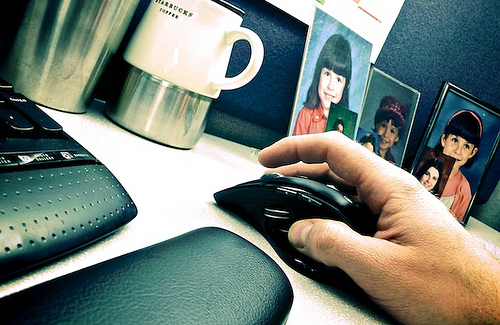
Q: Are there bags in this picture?
A: No, there are no bags.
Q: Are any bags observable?
A: No, there are no bags.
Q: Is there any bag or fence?
A: No, there are no bags or fences.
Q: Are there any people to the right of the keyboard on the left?
A: Yes, there is a person to the right of the keyboard.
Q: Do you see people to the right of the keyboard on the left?
A: Yes, there is a person to the right of the keyboard.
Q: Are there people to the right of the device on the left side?
A: Yes, there is a person to the right of the keyboard.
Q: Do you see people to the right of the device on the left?
A: Yes, there is a person to the right of the keyboard.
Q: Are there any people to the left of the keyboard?
A: No, the person is to the right of the keyboard.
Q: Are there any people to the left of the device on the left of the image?
A: No, the person is to the right of the keyboard.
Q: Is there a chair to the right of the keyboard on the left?
A: No, there is a person to the right of the keyboard.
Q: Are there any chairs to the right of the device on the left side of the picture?
A: No, there is a person to the right of the keyboard.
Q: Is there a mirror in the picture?
A: No, there are no mirrors.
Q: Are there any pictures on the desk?
A: Yes, there is a picture on the desk.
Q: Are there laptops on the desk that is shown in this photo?
A: No, there is a picture on the desk.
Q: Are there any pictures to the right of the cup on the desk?
A: Yes, there is a picture to the right of the cup.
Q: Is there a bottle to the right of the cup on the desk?
A: No, there is a picture to the right of the cup.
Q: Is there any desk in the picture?
A: Yes, there is a desk.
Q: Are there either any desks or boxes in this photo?
A: Yes, there is a desk.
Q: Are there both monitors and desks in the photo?
A: No, there is a desk but no monitors.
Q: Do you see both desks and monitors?
A: No, there is a desk but no monitors.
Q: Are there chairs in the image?
A: No, there are no chairs.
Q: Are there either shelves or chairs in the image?
A: No, there are no chairs or shelves.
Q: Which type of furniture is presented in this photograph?
A: The furniture is a desk.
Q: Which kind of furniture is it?
A: The piece of furniture is a desk.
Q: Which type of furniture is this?
A: This is a desk.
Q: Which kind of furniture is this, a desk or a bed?
A: This is a desk.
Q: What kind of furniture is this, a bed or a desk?
A: This is a desk.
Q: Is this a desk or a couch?
A: This is a desk.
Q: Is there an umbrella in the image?
A: No, there are no umbrellas.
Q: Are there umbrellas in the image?
A: No, there are no umbrellas.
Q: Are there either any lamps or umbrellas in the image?
A: No, there are no umbrellas or lamps.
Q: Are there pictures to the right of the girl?
A: Yes, there is a picture to the right of the girl.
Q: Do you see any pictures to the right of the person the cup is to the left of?
A: Yes, there is a picture to the right of the girl.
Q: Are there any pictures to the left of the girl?
A: No, the picture is to the right of the girl.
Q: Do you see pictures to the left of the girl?
A: No, the picture is to the right of the girl.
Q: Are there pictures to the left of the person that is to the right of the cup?
A: No, the picture is to the right of the girl.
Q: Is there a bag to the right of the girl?
A: No, there is a picture to the right of the girl.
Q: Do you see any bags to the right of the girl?
A: No, there is a picture to the right of the girl.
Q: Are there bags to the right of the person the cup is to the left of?
A: No, there is a picture to the right of the girl.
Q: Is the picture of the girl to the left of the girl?
A: No, the picture is to the right of the girl.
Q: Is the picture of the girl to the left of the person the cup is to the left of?
A: No, the picture is to the right of the girl.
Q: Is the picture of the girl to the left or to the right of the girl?
A: The picture is to the right of the girl.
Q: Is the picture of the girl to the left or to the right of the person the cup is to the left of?
A: The picture is to the right of the girl.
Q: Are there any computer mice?
A: Yes, there is a computer mouse.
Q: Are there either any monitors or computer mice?
A: Yes, there is a computer mouse.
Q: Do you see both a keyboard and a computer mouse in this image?
A: Yes, there are both a computer mouse and a keyboard.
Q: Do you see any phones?
A: No, there are no phones.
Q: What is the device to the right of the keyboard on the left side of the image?
A: The device is a computer mouse.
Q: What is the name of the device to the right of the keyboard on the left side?
A: The device is a computer mouse.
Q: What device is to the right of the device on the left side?
A: The device is a computer mouse.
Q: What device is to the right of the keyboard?
A: The device is a computer mouse.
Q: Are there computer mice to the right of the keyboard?
A: Yes, there is a computer mouse to the right of the keyboard.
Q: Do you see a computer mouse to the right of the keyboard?
A: Yes, there is a computer mouse to the right of the keyboard.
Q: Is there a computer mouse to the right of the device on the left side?
A: Yes, there is a computer mouse to the right of the keyboard.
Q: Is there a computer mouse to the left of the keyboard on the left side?
A: No, the computer mouse is to the right of the keyboard.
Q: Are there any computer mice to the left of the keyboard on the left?
A: No, the computer mouse is to the right of the keyboard.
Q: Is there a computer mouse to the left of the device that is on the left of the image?
A: No, the computer mouse is to the right of the keyboard.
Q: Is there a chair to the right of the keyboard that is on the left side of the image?
A: No, there is a computer mouse to the right of the keyboard.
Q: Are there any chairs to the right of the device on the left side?
A: No, there is a computer mouse to the right of the keyboard.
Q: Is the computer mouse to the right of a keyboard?
A: Yes, the computer mouse is to the right of a keyboard.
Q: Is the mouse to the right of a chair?
A: No, the mouse is to the right of a keyboard.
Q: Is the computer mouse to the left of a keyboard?
A: No, the computer mouse is to the right of a keyboard.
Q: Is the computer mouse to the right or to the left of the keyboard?
A: The computer mouse is to the right of the keyboard.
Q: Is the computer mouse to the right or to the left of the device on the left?
A: The computer mouse is to the right of the keyboard.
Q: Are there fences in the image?
A: No, there are no fences.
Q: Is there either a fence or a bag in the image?
A: No, there are no fences or bags.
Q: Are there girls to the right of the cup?
A: Yes, there is a girl to the right of the cup.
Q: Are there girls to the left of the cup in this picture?
A: No, the girl is to the right of the cup.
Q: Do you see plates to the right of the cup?
A: No, there is a girl to the right of the cup.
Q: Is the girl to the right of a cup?
A: Yes, the girl is to the right of a cup.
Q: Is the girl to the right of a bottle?
A: No, the girl is to the right of a cup.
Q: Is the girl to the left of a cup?
A: No, the girl is to the right of a cup.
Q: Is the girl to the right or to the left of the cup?
A: The girl is to the right of the cup.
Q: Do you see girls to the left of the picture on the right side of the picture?
A: Yes, there is a girl to the left of the picture.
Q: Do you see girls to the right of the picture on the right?
A: No, the girl is to the left of the picture.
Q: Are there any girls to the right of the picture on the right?
A: No, the girl is to the left of the picture.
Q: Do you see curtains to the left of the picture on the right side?
A: No, there is a girl to the left of the picture.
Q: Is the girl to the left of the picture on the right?
A: Yes, the girl is to the left of the picture.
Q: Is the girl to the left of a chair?
A: No, the girl is to the left of the picture.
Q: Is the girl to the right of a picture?
A: No, the girl is to the left of a picture.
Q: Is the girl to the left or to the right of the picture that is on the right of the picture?
A: The girl is to the left of the picture.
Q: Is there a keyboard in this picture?
A: Yes, there is a keyboard.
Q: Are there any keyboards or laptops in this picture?
A: Yes, there is a keyboard.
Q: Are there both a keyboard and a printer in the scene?
A: No, there is a keyboard but no printers.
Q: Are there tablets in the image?
A: No, there are no tablets.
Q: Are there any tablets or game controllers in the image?
A: No, there are no tablets or game controllers.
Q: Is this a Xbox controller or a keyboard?
A: This is a keyboard.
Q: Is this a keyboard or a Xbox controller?
A: This is a keyboard.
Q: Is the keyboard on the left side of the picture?
A: Yes, the keyboard is on the left of the image.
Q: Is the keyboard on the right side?
A: No, the keyboard is on the left of the image.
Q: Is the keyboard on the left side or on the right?
A: The keyboard is on the left of the image.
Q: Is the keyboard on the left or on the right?
A: The keyboard is on the left of the image.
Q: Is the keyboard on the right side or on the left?
A: The keyboard is on the left of the image.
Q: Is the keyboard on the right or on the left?
A: The keyboard is on the left of the image.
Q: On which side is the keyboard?
A: The keyboard is on the left of the image.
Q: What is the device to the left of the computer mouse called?
A: The device is a keyboard.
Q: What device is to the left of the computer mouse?
A: The device is a keyboard.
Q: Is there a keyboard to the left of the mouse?
A: Yes, there is a keyboard to the left of the mouse.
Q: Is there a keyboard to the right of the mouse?
A: No, the keyboard is to the left of the mouse.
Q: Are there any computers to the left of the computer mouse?
A: No, there is a keyboard to the left of the computer mouse.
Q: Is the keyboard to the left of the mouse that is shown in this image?
A: Yes, the keyboard is to the left of the mouse.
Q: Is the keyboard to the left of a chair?
A: No, the keyboard is to the left of the mouse.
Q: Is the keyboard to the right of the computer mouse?
A: No, the keyboard is to the left of the computer mouse.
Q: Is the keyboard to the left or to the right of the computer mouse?
A: The keyboard is to the left of the computer mouse.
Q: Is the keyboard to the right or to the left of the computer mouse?
A: The keyboard is to the left of the computer mouse.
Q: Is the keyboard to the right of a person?
A: No, the keyboard is to the left of a person.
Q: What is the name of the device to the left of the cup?
A: The device is a keyboard.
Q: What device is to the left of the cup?
A: The device is a keyboard.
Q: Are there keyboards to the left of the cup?
A: Yes, there is a keyboard to the left of the cup.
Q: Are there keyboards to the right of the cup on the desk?
A: No, the keyboard is to the left of the cup.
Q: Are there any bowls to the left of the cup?
A: No, there is a keyboard to the left of the cup.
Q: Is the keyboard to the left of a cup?
A: Yes, the keyboard is to the left of a cup.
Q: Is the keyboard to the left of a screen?
A: No, the keyboard is to the left of a cup.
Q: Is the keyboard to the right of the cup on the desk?
A: No, the keyboard is to the left of the cup.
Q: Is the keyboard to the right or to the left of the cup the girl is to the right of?
A: The keyboard is to the left of the cup.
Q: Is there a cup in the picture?
A: Yes, there is a cup.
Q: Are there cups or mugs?
A: Yes, there is a cup.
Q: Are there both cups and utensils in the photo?
A: No, there is a cup but no utensils.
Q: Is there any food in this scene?
A: No, there is no food.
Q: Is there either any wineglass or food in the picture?
A: No, there are no food or wine glasses.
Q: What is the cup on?
A: The cup is on the desk.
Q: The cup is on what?
A: The cup is on the desk.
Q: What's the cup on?
A: The cup is on the desk.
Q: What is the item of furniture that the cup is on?
A: The piece of furniture is a desk.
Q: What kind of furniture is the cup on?
A: The cup is on the desk.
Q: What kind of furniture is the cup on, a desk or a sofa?
A: The cup is on a desk.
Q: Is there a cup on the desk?
A: Yes, there is a cup on the desk.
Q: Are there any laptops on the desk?
A: No, there is a cup on the desk.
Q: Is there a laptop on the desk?
A: No, there is a cup on the desk.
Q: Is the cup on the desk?
A: Yes, the cup is on the desk.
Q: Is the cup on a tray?
A: No, the cup is on the desk.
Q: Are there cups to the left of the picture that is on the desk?
A: Yes, there is a cup to the left of the picture.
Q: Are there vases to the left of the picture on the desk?
A: No, there is a cup to the left of the picture.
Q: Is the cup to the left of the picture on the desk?
A: Yes, the cup is to the left of the picture.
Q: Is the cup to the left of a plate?
A: No, the cup is to the left of the picture.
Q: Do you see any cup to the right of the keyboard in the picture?
A: Yes, there is a cup to the right of the keyboard.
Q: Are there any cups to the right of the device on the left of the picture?
A: Yes, there is a cup to the right of the keyboard.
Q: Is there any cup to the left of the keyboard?
A: No, the cup is to the right of the keyboard.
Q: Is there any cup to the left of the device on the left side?
A: No, the cup is to the right of the keyboard.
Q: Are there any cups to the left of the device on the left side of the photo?
A: No, the cup is to the right of the keyboard.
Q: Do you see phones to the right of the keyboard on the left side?
A: No, there is a cup to the right of the keyboard.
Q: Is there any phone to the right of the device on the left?
A: No, there is a cup to the right of the keyboard.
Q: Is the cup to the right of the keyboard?
A: Yes, the cup is to the right of the keyboard.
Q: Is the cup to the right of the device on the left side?
A: Yes, the cup is to the right of the keyboard.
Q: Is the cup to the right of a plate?
A: No, the cup is to the right of the keyboard.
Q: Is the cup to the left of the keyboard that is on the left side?
A: No, the cup is to the right of the keyboard.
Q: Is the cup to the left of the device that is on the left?
A: No, the cup is to the right of the keyboard.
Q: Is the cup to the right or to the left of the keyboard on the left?
A: The cup is to the right of the keyboard.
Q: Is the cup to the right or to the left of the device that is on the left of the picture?
A: The cup is to the right of the keyboard.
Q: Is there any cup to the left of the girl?
A: Yes, there is a cup to the left of the girl.